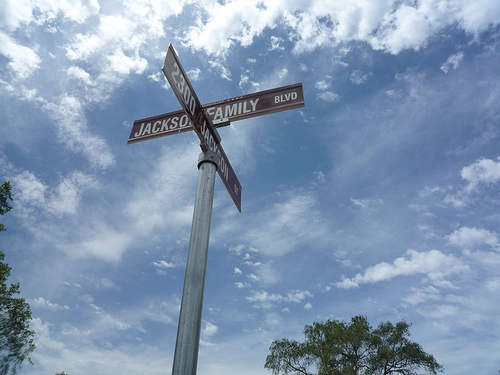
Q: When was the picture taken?
A: Daytime.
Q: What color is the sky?
A: Blue.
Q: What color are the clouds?
A: White.